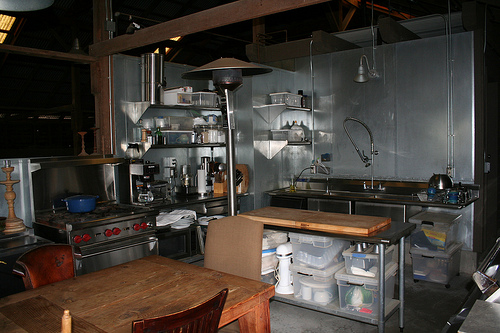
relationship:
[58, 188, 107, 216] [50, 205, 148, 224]
pot on stove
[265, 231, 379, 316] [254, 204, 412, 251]
containers under counter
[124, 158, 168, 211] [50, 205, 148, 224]
coffee maker beside stove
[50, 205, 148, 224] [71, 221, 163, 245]
stove has knobs